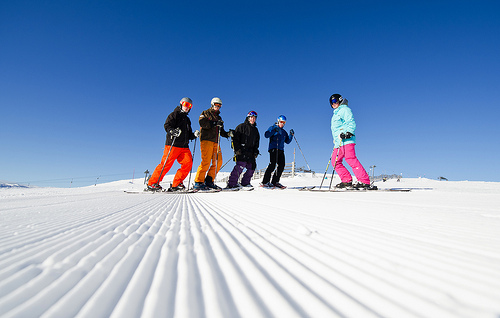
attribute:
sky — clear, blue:
[261, 26, 339, 56]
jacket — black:
[163, 114, 193, 144]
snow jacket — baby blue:
[330, 105, 358, 147]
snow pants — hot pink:
[320, 140, 372, 200]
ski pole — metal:
[306, 151, 347, 199]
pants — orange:
[193, 139, 225, 183]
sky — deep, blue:
[266, 35, 383, 74]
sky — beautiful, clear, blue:
[2, 0, 497, 200]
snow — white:
[1, 172, 498, 314]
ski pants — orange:
[192, 138, 222, 183]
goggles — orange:
[179, 100, 191, 112]